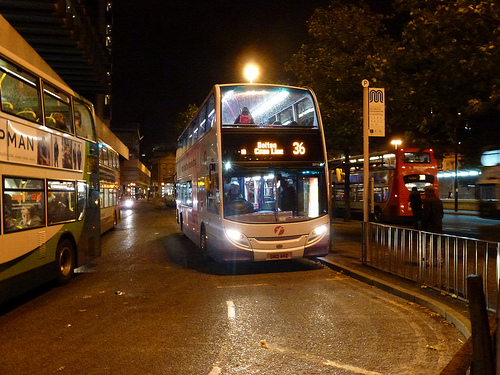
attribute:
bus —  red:
[317, 147, 442, 221]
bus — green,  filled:
[4, 17, 103, 289]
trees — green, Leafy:
[281, 2, 496, 148]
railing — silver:
[357, 217, 498, 314]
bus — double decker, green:
[6, 54, 136, 300]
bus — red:
[331, 145, 433, 220]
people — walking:
[420, 185, 445, 265]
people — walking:
[406, 184, 422, 229]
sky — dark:
[109, 33, 276, 39]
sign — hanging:
[368, 87, 388, 139]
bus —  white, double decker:
[145, 61, 348, 270]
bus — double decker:
[172, 77, 332, 259]